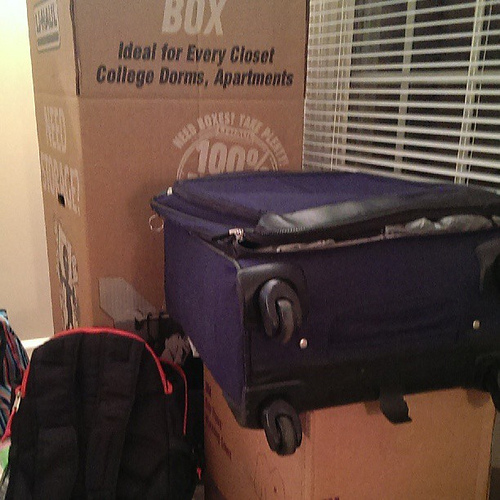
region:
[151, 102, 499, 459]
a blue suitcase open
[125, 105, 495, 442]
a blue suit case on a box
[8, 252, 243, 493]
a black and pink backpack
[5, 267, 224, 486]
a black and pink bag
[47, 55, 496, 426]
brown boxes next to each other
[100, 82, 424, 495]
suitcase on a box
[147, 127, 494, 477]
suitcase on a brown box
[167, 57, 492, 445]
suitcase in front of blindes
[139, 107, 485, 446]
suitcase in front of window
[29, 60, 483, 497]
boxes in front of window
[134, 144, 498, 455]
a blue suitcase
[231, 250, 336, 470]
wheels on left side of suitcase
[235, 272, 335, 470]
wheels are black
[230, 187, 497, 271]
suitcase is open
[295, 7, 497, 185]
window is covered with blinds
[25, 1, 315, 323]
big box in a room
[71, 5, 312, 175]
letters on brown box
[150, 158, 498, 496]
suitcase on cart over cardboard box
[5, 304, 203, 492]
a backpack is black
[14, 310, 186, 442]
backpack has red border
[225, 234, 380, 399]
the trolley is blue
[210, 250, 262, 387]
the trolley is blue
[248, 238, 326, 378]
the trolley is blue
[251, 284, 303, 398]
the trolley is blue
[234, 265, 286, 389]
the trolley is blue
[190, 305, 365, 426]
the trolley is blue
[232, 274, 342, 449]
the trolley is blue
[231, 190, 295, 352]
the trolley is blue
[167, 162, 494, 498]
a small piece of luggage sitting on a box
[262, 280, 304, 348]
a wheel on a small piece of luggage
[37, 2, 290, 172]
a large cardboard box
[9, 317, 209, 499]
a backpack sitting on the floor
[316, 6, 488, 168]
white horizontal blinds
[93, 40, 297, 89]
printing on a box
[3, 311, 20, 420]
a multicolored cloth bag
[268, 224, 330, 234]
the teeth of a zipper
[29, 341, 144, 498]
the straps of a backpack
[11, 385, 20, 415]
the zipper of a backpack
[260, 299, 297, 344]
wheel on bottom of suitcase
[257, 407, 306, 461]
wheel on bottom of suitcase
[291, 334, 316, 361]
metal piece on bottom of suitcase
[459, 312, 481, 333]
metal piece on bottom of suitcase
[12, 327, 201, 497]
book bag on floor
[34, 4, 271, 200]
cardboard box in corner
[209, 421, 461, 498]
cardboard box on floor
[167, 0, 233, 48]
box in white text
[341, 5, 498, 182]
white blinds on window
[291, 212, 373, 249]
open zipper on suitcase